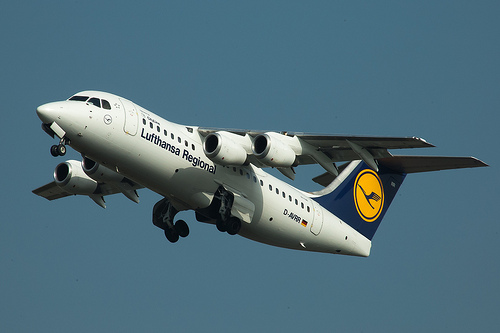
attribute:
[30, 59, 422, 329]
plane — airborne, taking off, white, flying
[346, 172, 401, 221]
flag — german, circle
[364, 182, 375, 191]
picture — yellow, bird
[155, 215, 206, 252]
wheel — folding,   two,  the front, lifted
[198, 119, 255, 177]
engine — white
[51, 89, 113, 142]
cock pit — glass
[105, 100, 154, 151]
door — white, closed, open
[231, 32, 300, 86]
sky — blue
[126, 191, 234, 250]
gear — landing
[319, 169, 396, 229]
logo — yellow, bird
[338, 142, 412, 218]
symbol — dark